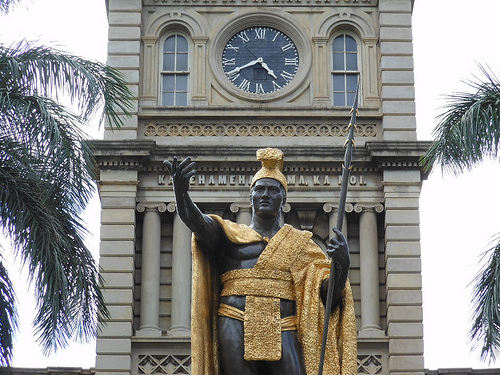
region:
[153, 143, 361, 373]
a statue with the right hand extended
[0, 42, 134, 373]
a palm tree on the statue's right side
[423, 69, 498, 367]
a palm tree on the statue's left side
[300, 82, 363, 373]
the statue is holding a weapon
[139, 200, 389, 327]
a row of columns on a building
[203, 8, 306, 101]
roman numerals on a clock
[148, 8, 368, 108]
two windows next to the clock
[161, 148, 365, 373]
a statue of an ancient warrior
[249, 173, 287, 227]
the statue has a serious expression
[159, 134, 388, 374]
a statue in front of a building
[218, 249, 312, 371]
Silver ropes on statute.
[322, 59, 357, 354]
Black stick on statue.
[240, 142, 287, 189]
Gold head band on statue.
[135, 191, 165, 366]
Column on the building.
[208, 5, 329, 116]
Big black clock on building.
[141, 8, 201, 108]
Curved window on the building.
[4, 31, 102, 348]
Trees to the left.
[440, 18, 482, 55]
Clear sky above trees.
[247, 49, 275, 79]
White second hand on the clock.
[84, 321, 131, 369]
Tan blocks on the building.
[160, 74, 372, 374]
A human statue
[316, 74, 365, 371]
Spear in the human statue's left hand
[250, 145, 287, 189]
Gold hat on the human statue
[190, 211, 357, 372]
Gold robe on the human statue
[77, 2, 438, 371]
White building behind the statue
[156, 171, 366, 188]
Words on the building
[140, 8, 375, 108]
Windows on the building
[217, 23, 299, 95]
Clock on the building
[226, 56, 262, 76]
Minute hand on the clock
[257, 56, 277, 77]
Hour hand on the clock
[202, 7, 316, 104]
Clock with a black face and white numerals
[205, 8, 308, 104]
Large clock with roman numerals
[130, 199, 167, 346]
Decorate stone columns as part of building architecture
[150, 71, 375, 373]
A statue in golden robes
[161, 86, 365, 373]
statue holding a sword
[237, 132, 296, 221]
Statue with a gold helmet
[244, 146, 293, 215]
Roman-style helmet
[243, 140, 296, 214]
Galea helmet with a "broom like" accessory on top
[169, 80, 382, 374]
statue with hand raise in hair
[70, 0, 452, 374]
Building with a large clock in its architecture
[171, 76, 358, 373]
statue of King Kamehameha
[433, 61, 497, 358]
palm fronds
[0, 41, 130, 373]
palm fronds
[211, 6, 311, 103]
clock on face of building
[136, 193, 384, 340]
decorative architectural columns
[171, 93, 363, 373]
statue of King Kamehameha dressed in king's clothes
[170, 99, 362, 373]
King Kamehameha with spear in left hand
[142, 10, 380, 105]
two windows in face of buildign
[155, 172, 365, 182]
letters on Ali'iolani Hale KAMEHAMEHA ELIMA NA MOI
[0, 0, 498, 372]
statue of King Kamehameha in front of Ali'iolani Hale